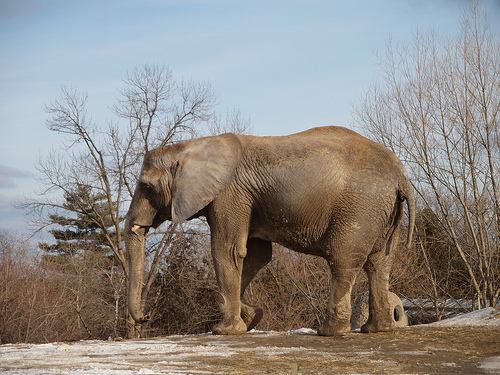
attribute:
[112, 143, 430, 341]
elephant — brown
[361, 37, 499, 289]
tree — bare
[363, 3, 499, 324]
tree — bare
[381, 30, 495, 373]
tree — bare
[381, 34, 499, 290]
tree — bare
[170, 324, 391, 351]
dirt — brown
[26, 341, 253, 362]
dirt — brown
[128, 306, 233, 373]
dirt — brown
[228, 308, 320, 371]
dirt — brown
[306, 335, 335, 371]
dirt — brown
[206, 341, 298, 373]
dirt — brown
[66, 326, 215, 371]
dirt — brown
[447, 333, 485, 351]
dirt patch — small, brown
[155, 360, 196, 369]
dirt patch — brown, small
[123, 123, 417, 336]
animal — walking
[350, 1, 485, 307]
tree — bare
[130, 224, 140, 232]
tusk — short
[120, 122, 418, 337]
elephant — gray, walking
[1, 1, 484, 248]
sky — cloudless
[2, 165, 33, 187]
cloud — sparse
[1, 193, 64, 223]
cloud — sparse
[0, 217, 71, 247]
cloud — sparse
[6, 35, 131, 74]
cloud — sparse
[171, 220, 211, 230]
cloud — sparse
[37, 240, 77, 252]
branch — green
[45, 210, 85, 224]
branch — green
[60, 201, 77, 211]
branch — green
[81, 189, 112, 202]
branch — green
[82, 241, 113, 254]
branch — green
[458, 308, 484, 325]
hill — small, little